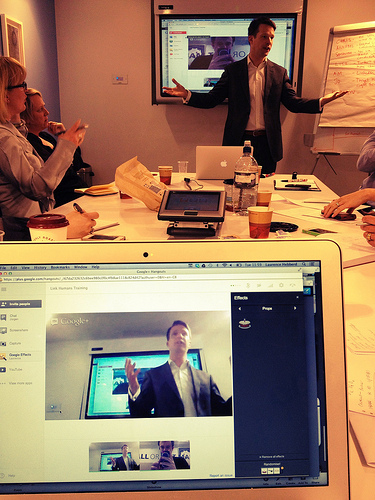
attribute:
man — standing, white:
[173, 6, 324, 167]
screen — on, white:
[158, 14, 300, 104]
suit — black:
[199, 60, 303, 158]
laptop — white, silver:
[191, 141, 252, 183]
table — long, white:
[0, 167, 368, 498]